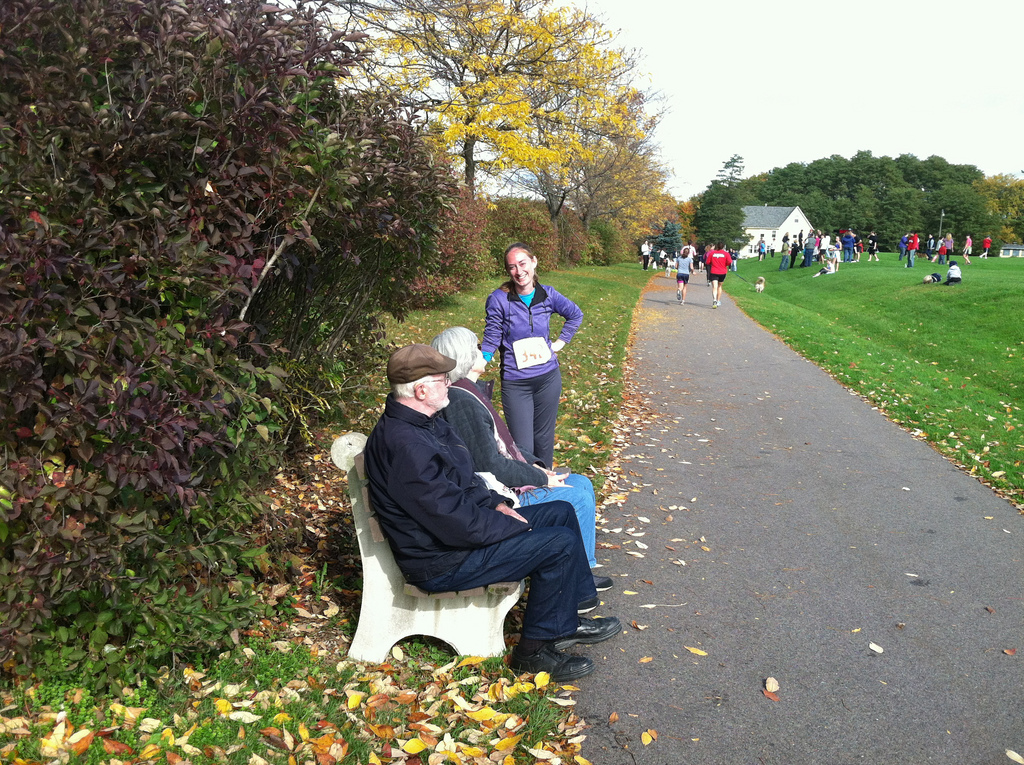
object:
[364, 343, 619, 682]
man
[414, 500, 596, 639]
pants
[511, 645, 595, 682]
boots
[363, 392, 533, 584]
jacket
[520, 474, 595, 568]
pants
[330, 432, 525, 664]
bench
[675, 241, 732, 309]
two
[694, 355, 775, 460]
cement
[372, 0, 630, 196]
tree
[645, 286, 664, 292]
leaves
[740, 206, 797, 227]
roof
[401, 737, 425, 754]
fallen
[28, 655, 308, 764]
grass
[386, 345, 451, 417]
head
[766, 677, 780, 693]
leaves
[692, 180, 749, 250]
trees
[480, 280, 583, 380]
jacket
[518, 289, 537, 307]
underneath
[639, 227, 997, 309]
group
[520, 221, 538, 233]
flowers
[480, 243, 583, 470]
woman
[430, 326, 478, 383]
hair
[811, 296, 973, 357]
grass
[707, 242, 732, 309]
man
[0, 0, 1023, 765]
park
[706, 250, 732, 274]
shirt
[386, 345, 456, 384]
hat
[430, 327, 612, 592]
lady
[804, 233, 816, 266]
people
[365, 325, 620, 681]
couple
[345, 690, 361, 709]
leaves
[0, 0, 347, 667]
bush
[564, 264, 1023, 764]
concrete path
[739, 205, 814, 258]
building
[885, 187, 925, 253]
evergreens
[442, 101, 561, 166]
autumn leaves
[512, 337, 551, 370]
paper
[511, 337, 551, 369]
number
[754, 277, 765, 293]
dog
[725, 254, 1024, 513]
fields